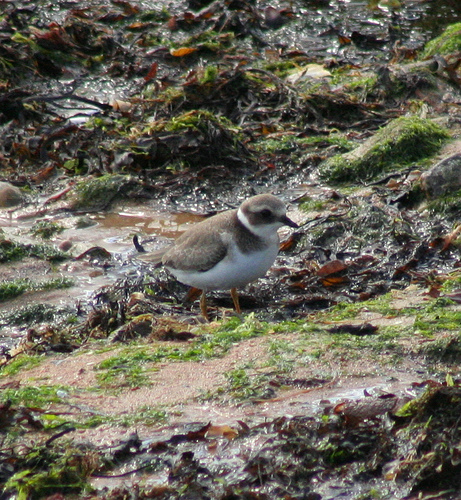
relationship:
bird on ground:
[131, 190, 299, 326] [174, 361, 339, 409]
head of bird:
[238, 193, 298, 232] [120, 194, 297, 313]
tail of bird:
[135, 241, 161, 276] [106, 179, 335, 325]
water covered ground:
[0, 0, 458, 497] [1, 0, 460, 497]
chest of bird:
[213, 228, 295, 289] [159, 194, 361, 315]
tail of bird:
[133, 234, 148, 253] [151, 171, 299, 333]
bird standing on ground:
[131, 190, 299, 326] [159, 346, 329, 406]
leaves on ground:
[284, 80, 358, 101] [149, 365, 311, 408]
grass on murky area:
[178, 62, 289, 121] [331, 204, 386, 239]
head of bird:
[246, 194, 284, 229] [131, 190, 299, 326]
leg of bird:
[194, 291, 210, 326] [144, 192, 348, 337]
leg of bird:
[227, 293, 245, 319] [144, 192, 348, 337]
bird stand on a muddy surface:
[131, 192, 299, 321] [2, 2, 459, 498]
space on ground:
[164, 342, 241, 388] [85, 297, 339, 463]